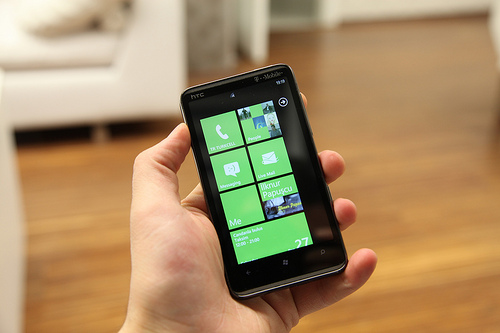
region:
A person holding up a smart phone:
[106, 55, 386, 331]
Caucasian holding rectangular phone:
[102, 51, 385, 329]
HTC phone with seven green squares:
[166, 57, 379, 320]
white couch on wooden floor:
[7, 0, 183, 177]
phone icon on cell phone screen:
[176, 59, 369, 301]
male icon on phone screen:
[163, 56, 366, 314]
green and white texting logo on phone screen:
[167, 57, 362, 304]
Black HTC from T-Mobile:
[169, 54, 366, 311]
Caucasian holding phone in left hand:
[73, 51, 412, 332]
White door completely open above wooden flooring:
[198, 0, 411, 87]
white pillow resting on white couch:
[9, 1, 210, 147]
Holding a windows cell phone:
[174, 63, 349, 299]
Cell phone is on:
[167, 74, 351, 311]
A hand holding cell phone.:
[127, 90, 375, 332]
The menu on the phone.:
[195, 96, 316, 278]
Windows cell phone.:
[175, 60, 352, 317]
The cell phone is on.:
[174, 68, 356, 298]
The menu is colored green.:
[196, 99, 316, 262]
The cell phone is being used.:
[131, 58, 383, 330]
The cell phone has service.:
[224, 89, 249, 101]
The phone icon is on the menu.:
[195, 106, 252, 158]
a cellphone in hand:
[157, 44, 384, 324]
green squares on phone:
[202, 95, 319, 262]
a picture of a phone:
[210, 112, 237, 144]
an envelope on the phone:
[248, 147, 295, 175]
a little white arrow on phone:
[277, 90, 294, 111]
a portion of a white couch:
[3, 1, 216, 152]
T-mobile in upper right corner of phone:
[243, 64, 293, 86]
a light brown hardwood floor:
[35, 10, 497, 327]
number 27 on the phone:
[281, 232, 320, 252]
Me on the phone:
[225, 209, 242, 234]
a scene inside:
[1, 5, 498, 325]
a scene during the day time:
[3, 1, 498, 326]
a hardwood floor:
[4, 30, 494, 331]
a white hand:
[107, 52, 374, 332]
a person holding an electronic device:
[92, 52, 419, 332]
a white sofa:
[5, 0, 205, 139]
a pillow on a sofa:
[18, 0, 148, 47]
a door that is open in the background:
[232, 0, 349, 72]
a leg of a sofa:
[86, 106, 134, 167]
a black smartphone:
[177, 52, 362, 295]